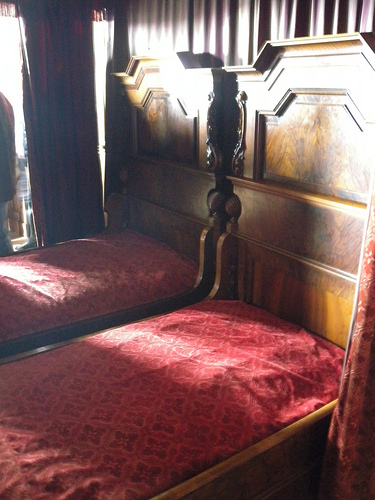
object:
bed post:
[97, 33, 374, 350]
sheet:
[0, 226, 220, 357]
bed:
[0, 51, 222, 352]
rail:
[0, 0, 122, 20]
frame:
[149, 395, 342, 498]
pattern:
[0, 225, 345, 498]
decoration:
[200, 95, 264, 299]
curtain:
[14, 3, 106, 247]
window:
[0, 1, 111, 246]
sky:
[0, 17, 25, 91]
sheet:
[0, 297, 349, 499]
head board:
[105, 53, 224, 264]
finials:
[194, 67, 245, 302]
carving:
[202, 97, 249, 176]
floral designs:
[196, 400, 216, 421]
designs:
[195, 375, 223, 395]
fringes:
[0, 0, 122, 18]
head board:
[205, 30, 374, 351]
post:
[196, 69, 219, 285]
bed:
[0, 34, 373, 498]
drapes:
[316, 195, 374, 498]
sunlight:
[0, 258, 66, 300]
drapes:
[105, 1, 374, 68]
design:
[251, 83, 366, 213]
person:
[0, 92, 15, 259]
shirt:
[0, 90, 14, 202]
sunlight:
[166, 51, 206, 111]